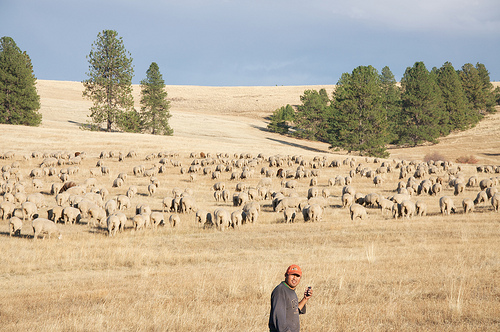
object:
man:
[267, 263, 316, 331]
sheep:
[212, 181, 225, 191]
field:
[5, 121, 499, 332]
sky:
[174, 13, 424, 53]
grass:
[201, 94, 256, 118]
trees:
[321, 64, 392, 159]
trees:
[399, 60, 451, 147]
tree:
[137, 61, 174, 137]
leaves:
[344, 72, 353, 82]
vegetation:
[173, 94, 204, 109]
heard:
[362, 212, 372, 220]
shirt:
[267, 281, 308, 332]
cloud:
[413, 8, 452, 34]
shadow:
[264, 136, 330, 155]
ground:
[0, 89, 257, 137]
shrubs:
[296, 88, 332, 114]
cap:
[284, 264, 303, 277]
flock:
[255, 152, 370, 199]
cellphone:
[306, 286, 312, 297]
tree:
[80, 28, 140, 133]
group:
[329, 59, 498, 158]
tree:
[0, 34, 43, 127]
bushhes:
[261, 104, 297, 136]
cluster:
[0, 148, 499, 239]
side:
[1, 3, 50, 168]